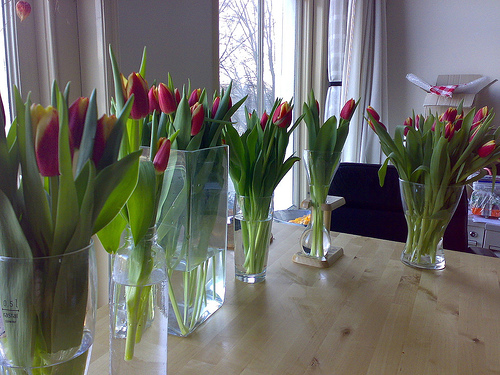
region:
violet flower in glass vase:
[27, 94, 72, 186]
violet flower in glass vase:
[88, 124, 112, 170]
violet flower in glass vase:
[147, 132, 191, 183]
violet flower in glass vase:
[123, 74, 152, 124]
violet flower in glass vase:
[159, 75, 174, 115]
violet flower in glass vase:
[192, 95, 205, 134]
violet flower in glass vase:
[259, 100, 305, 135]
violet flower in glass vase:
[338, 87, 351, 127]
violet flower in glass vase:
[434, 107, 469, 137]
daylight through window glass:
[218, 0, 294, 217]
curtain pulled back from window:
[323, 0, 387, 163]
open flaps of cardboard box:
[412, 70, 492, 115]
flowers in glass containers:
[0, 68, 493, 373]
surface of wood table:
[74, 221, 499, 373]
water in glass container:
[108, 266, 169, 371]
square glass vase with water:
[131, 144, 229, 334]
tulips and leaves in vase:
[0, 84, 136, 370]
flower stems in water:
[237, 214, 272, 274]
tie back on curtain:
[326, 78, 344, 90]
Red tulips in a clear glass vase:
[349, 88, 499, 280]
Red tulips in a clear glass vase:
[293, 135, 350, 266]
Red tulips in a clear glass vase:
[232, 85, 296, 288]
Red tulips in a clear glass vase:
[175, 80, 231, 337]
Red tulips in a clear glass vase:
[3, 70, 99, 365]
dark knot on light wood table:
[327, 319, 360, 349]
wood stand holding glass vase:
[291, 183, 350, 272]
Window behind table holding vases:
[213, 5, 306, 81]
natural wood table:
[62, 216, 498, 373]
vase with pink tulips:
[365, 98, 494, 272]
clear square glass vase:
[139, 138, 229, 335]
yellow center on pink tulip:
[30, 103, 55, 147]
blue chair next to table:
[327, 157, 417, 246]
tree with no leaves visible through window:
[222, 3, 280, 118]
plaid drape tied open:
[322, 2, 387, 164]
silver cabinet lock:
[468, 228, 478, 240]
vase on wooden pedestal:
[290, 190, 347, 266]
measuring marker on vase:
[0, 293, 23, 326]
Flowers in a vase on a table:
[132, 70, 246, 335]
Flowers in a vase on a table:
[361, 83, 491, 327]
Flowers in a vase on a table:
[282, 83, 367, 265]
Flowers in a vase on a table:
[229, 87, 292, 259]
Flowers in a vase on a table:
[107, 108, 211, 370]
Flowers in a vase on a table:
[22, 120, 155, 369]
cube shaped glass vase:
[137, 143, 227, 337]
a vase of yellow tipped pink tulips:
[0, 80, 141, 373]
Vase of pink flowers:
[364, 101, 499, 269]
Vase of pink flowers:
[222, 95, 309, 284]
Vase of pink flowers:
[137, 74, 249, 338]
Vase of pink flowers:
[0, 80, 143, 373]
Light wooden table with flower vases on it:
[0, 216, 499, 373]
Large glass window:
[219, 1, 300, 222]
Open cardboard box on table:
[404, 66, 497, 132]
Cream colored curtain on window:
[341, 1, 389, 165]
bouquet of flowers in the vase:
[379, 73, 496, 271]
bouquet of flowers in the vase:
[297, 76, 362, 279]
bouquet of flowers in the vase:
[220, 73, 288, 289]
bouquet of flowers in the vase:
[132, 72, 234, 345]